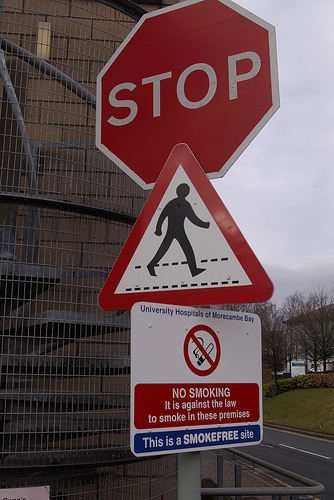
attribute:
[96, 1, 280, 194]
stop sign — red, white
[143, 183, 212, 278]
figure — a human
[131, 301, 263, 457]
no smoking sign — smokefree site sign, partly blue, white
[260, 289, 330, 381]
trees — dead, without leaves, leafless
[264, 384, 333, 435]
grass — green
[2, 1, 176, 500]
building — caged, multi story, tall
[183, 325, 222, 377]
no smoking picture — cigarette with line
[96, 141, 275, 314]
sign — red, a walk sign, pedestrian crossing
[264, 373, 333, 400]
bushes — brown, green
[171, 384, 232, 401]
no smoking — white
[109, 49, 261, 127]
letters — the word "stop", white